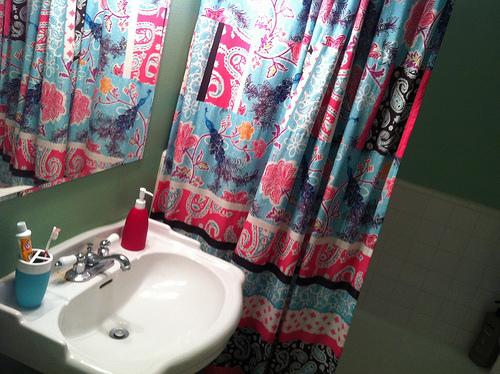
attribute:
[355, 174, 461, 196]
wall — printed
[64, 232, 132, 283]
faucet — silver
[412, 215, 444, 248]
tile — white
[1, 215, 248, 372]
sink — white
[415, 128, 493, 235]
wall — white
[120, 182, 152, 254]
soap — red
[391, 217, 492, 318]
wall — white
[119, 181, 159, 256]
bottle — red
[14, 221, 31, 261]
toothpaste — white, orange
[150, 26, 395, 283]
pattern — flower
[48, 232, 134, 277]
faucet — chrome, bathroom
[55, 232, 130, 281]
faucet — chrome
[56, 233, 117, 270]
handles — white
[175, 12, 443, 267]
curtain — pink, blue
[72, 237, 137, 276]
faucet — sink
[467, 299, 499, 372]
bottle — shampoo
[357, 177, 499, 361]
tiles — white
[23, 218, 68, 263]
toothbrush — white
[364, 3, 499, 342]
bathroom wall — green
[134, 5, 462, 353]
curtain — shower